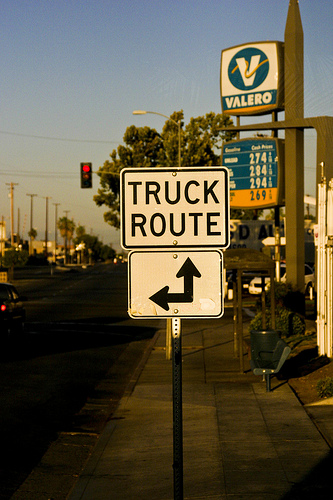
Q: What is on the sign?
A: Words.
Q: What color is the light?
A: Red.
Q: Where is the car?
A: On the street.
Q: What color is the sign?
A: White.